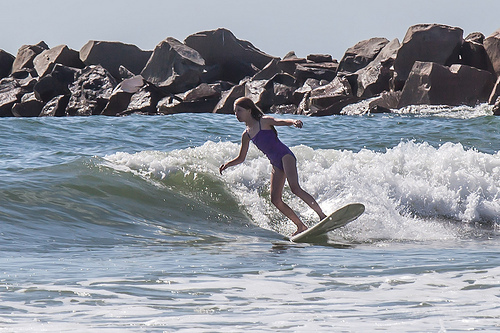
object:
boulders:
[0, 24, 499, 117]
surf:
[100, 97, 497, 246]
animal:
[120, 72, 183, 117]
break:
[96, 140, 500, 244]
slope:
[0, 113, 497, 148]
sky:
[2, 1, 497, 65]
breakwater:
[104, 137, 500, 248]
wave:
[10, 133, 497, 254]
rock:
[356, 23, 464, 98]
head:
[233, 95, 259, 123]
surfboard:
[289, 202, 369, 240]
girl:
[217, 95, 330, 236]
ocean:
[0, 105, 499, 333]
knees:
[266, 196, 285, 206]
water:
[0, 105, 500, 333]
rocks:
[391, 59, 497, 110]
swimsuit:
[253, 131, 293, 171]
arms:
[218, 134, 253, 175]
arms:
[269, 118, 305, 128]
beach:
[0, 103, 495, 118]